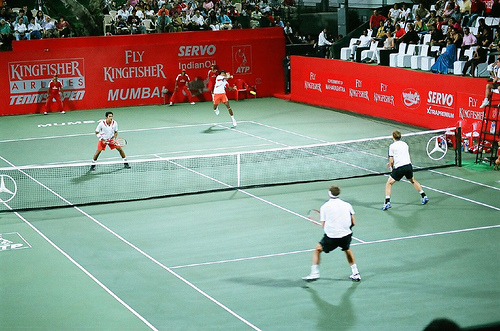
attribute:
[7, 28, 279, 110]
wall — red, white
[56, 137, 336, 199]
tennis net — black, white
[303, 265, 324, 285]
shoe — white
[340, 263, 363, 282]
shoe — white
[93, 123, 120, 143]
shirt — white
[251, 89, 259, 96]
ball — flying through air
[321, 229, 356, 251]
shorts — black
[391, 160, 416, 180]
shorts — black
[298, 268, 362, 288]
shoes — black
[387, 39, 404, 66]
chair — white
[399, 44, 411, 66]
chair — white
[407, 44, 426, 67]
chair — white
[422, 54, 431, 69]
chair — white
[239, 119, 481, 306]
men — playing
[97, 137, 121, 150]
shorts — red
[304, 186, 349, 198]
headband — white